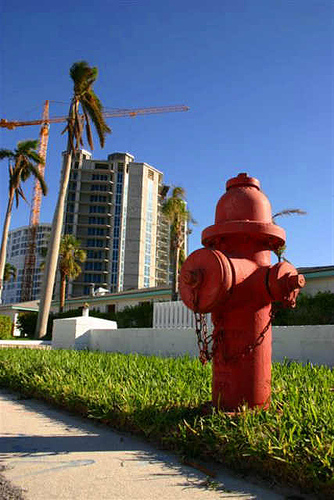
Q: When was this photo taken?
A: Daytime.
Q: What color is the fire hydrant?
A: Red.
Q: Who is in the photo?
A: No one.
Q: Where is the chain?
A: On the hydrant.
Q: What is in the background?
A: Skyscrapers.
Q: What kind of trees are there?
A: Palm trees.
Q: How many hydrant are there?
A: One.